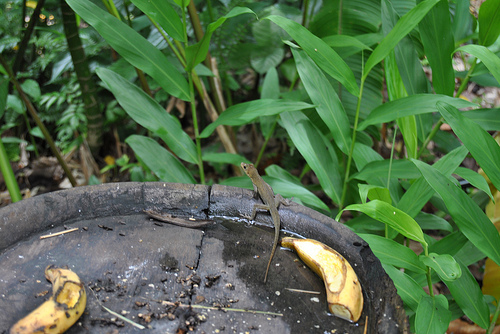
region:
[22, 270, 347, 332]
2 bananas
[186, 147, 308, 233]
small lizard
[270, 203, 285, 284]
long tail on lizard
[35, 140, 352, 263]
lizard sitting on dark circular wood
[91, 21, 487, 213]
green lush leaves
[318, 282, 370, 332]
end of the banana is cut off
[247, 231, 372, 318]
banana is yellow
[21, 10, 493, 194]
lots of greenery in the background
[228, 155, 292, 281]
lizard is same size as banana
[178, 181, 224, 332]
crack down the middle of the wood object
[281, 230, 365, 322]
Half a banana.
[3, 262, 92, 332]
Rotten half of a banana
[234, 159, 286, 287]
Little lizard that blends in.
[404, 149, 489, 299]
Green leaves to weeds.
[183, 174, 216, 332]
Crack down the black object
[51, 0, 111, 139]
Thick green trunk of a plant.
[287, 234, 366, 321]
Half a banana laying on the black base.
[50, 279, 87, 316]
Rotten place on a banana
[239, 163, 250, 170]
Little black eye of a lizard.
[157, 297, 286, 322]
Piece of green grass.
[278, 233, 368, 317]
this is a banana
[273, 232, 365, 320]
the banana is yellow in color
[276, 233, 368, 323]
the banana is on water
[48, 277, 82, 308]
the banana is bitten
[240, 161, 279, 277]
this is a lizard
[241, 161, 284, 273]
the lizard is staring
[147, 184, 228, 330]
the stand has a crack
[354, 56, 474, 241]
the eaves are green in color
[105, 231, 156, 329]
the stand is black in color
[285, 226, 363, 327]
the banana is ripe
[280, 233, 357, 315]
the banana is small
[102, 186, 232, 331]
the stand is old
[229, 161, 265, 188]
the lizard is gazing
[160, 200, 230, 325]
the stand has crack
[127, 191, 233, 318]
the stand is black in color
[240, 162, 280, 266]
the lizard is green in color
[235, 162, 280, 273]
the lizard is long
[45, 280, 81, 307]
this banana is bitten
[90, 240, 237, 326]
the stand is black in color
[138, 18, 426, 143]
the leaves are green in color